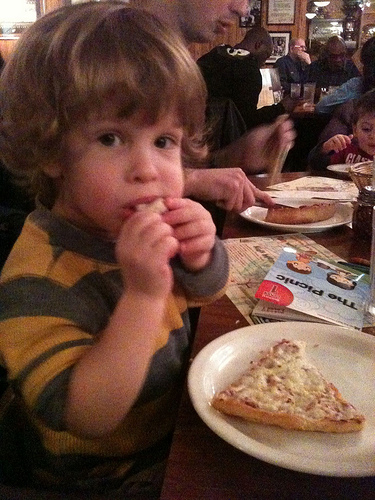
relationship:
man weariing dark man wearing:
[200, 26, 288, 136] [191, 26, 285, 131]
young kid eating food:
[4, 60, 217, 488] [225, 334, 361, 441]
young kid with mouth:
[4, 60, 217, 488] [116, 192, 163, 217]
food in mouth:
[131, 195, 186, 227] [116, 192, 163, 217]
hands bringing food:
[109, 201, 230, 291] [129, 190, 174, 225]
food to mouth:
[129, 190, 174, 225] [123, 188, 177, 224]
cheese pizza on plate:
[219, 321, 360, 462] [180, 292, 373, 461]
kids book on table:
[254, 234, 368, 329] [179, 154, 373, 479]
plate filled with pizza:
[182, 315, 373, 480] [216, 321, 367, 434]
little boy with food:
[7, 50, 231, 485] [124, 190, 177, 225]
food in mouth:
[124, 190, 177, 225] [119, 184, 172, 222]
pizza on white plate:
[229, 326, 366, 445] [183, 301, 373, 475]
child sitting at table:
[7, 0, 238, 494] [159, 166, 373, 495]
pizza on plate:
[205, 336, 367, 440] [182, 315, 373, 480]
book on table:
[246, 225, 373, 335] [159, 166, 373, 495]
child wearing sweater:
[7, 0, 238, 494] [4, 195, 231, 480]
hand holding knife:
[186, 161, 271, 213] [270, 189, 370, 209]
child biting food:
[7, 0, 238, 494] [133, 200, 168, 216]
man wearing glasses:
[273, 35, 313, 82] [286, 42, 306, 49]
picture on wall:
[235, 0, 264, 30] [235, 0, 372, 44]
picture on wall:
[264, 2, 297, 26] [235, 0, 372, 44]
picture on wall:
[262, 28, 294, 69] [235, 0, 372, 44]